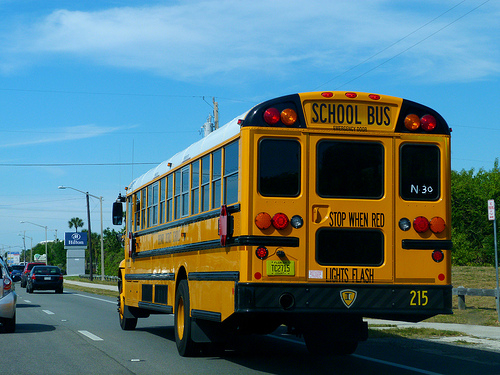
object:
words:
[382, 104, 394, 122]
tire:
[171, 278, 224, 355]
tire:
[116, 269, 138, 329]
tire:
[306, 330, 369, 354]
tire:
[1, 294, 19, 333]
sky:
[18, 11, 288, 188]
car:
[25, 263, 66, 293]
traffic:
[13, 253, 299, 338]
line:
[76, 329, 107, 343]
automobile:
[111, 91, 452, 355]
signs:
[153, 228, 191, 246]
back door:
[307, 132, 397, 285]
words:
[367, 270, 371, 282]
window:
[257, 137, 301, 199]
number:
[406, 291, 419, 307]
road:
[3, 279, 441, 371]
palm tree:
[67, 219, 82, 231]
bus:
[397, 249, 457, 304]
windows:
[313, 140, 385, 198]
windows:
[393, 141, 441, 201]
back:
[240, 91, 453, 321]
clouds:
[192, 19, 240, 51]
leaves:
[443, 157, 498, 269]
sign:
[63, 232, 86, 248]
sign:
[485, 197, 499, 220]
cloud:
[43, 15, 112, 48]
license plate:
[265, 258, 298, 276]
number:
[421, 289, 430, 303]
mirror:
[113, 204, 124, 224]